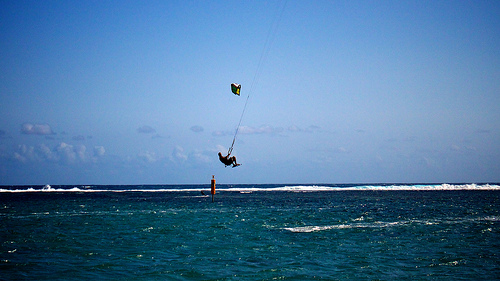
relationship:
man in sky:
[211, 148, 262, 172] [71, 14, 146, 74]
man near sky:
[211, 148, 262, 172] [71, 14, 146, 74]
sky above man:
[71, 14, 146, 74] [211, 148, 262, 172]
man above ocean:
[211, 148, 262, 172] [99, 213, 155, 251]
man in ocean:
[211, 148, 262, 172] [99, 213, 155, 251]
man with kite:
[211, 148, 262, 172] [227, 68, 249, 104]